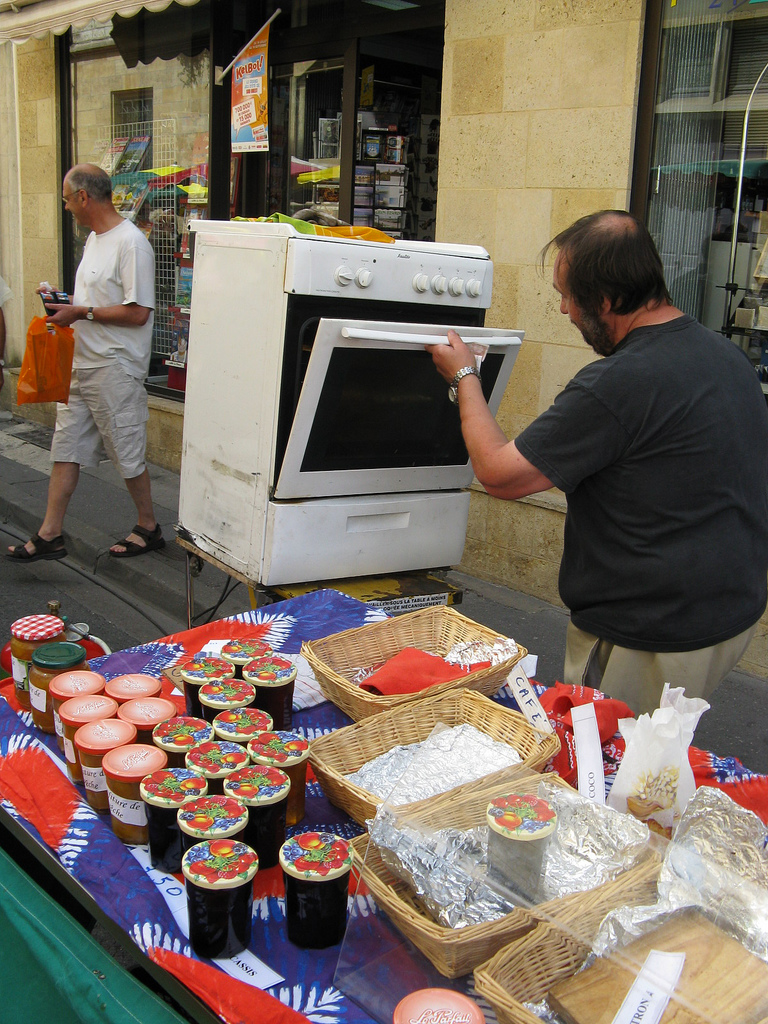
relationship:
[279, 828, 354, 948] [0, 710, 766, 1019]
jar on table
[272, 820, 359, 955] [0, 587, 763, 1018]
jar on table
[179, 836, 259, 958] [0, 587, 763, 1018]
jar on table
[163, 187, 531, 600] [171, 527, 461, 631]
oven on cart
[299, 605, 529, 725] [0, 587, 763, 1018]
basket on table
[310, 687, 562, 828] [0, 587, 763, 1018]
basket on table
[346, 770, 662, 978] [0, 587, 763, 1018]
basket on table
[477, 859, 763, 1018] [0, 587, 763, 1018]
basket on table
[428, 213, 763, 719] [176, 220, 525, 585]
man opening oven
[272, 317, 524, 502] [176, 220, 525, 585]
door on oven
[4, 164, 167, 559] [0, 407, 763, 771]
man walking on sidewalk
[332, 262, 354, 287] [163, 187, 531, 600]
knob on oven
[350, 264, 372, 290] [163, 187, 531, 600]
knob on oven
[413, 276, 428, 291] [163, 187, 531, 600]
knob on oven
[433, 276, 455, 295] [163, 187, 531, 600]
knob on oven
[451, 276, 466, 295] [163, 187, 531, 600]
knob on oven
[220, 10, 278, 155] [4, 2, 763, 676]
flag on building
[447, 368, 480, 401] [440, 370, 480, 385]
watch on wrist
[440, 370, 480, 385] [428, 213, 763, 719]
wrist of man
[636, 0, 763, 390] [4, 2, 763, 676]
window on building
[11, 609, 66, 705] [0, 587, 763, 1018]
jar on table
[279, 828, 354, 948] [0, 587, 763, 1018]
jar on table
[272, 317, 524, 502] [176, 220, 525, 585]
door of oven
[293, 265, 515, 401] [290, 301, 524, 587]
handle on door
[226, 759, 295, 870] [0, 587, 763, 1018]
jar on table